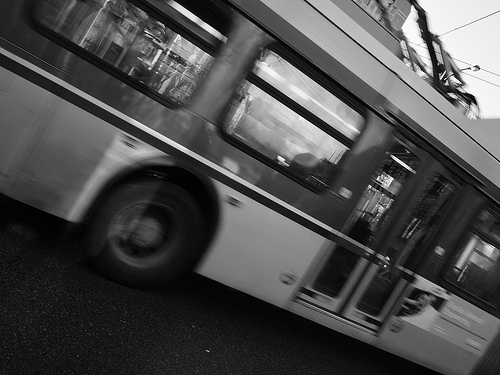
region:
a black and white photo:
[5, 1, 497, 343]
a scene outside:
[7, 11, 491, 371]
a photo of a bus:
[9, 3, 497, 373]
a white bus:
[3, 5, 494, 340]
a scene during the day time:
[3, 8, 494, 373]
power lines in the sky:
[386, 0, 498, 104]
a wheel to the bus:
[53, 139, 238, 307]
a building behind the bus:
[317, 1, 431, 71]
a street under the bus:
[16, 229, 390, 373]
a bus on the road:
[64, 44, 350, 360]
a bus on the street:
[55, 90, 433, 364]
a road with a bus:
[173, 136, 417, 368]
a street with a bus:
[200, 169, 375, 374]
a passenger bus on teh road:
[1, 53, 326, 355]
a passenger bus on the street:
[10, 19, 460, 364]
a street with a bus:
[54, 64, 383, 374]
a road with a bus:
[47, 79, 362, 371]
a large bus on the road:
[107, 34, 403, 374]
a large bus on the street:
[136, 58, 435, 374]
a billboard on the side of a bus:
[401, 271, 495, 353]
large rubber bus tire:
[88, 166, 215, 289]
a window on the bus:
[222, 44, 377, 190]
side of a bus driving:
[5, 6, 499, 369]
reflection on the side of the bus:
[67, 99, 274, 239]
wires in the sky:
[405, 4, 499, 93]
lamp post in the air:
[460, 63, 483, 76]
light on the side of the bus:
[222, 195, 242, 208]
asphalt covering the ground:
[7, 220, 356, 373]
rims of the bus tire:
[111, 200, 176, 265]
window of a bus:
[67, 17, 167, 67]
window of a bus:
[143, 35, 217, 96]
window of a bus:
[210, 24, 293, 143]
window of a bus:
[292, 63, 336, 103]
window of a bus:
[260, 120, 312, 167]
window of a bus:
[311, 130, 362, 185]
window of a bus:
[320, 92, 372, 137]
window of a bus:
[342, 122, 420, 227]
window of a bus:
[302, 258, 377, 307]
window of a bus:
[437, 234, 494, 307]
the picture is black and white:
[0, 5, 498, 364]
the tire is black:
[70, 167, 205, 302]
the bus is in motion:
[0, 3, 467, 355]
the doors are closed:
[285, 116, 489, 344]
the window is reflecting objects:
[222, 49, 356, 199]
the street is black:
[28, 275, 208, 366]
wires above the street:
[404, 6, 488, 100]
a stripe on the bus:
[1, 97, 369, 266]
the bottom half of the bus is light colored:
[0, 132, 470, 367]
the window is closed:
[202, 39, 360, 221]